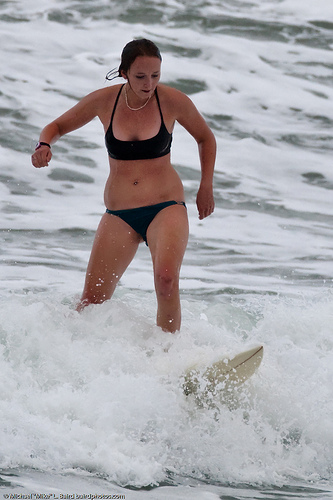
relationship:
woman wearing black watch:
[31, 34, 216, 334] [34, 141, 51, 150]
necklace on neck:
[124, 102, 144, 115] [125, 80, 135, 99]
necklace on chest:
[124, 102, 144, 115] [119, 115, 169, 142]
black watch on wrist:
[34, 141, 50, 150] [28, 137, 55, 154]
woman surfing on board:
[29, 34, 217, 335] [180, 343, 267, 401]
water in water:
[1, 0, 331, 496] [9, 38, 328, 467]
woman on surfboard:
[29, 34, 217, 335] [179, 339, 271, 401]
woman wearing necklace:
[31, 34, 216, 334] [121, 81, 152, 111]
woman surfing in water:
[29, 34, 217, 335] [284, 155, 318, 197]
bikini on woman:
[95, 199, 190, 240] [11, 23, 257, 278]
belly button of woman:
[129, 169, 152, 201] [29, 32, 231, 349]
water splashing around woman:
[1, 0, 332, 499] [31, 34, 216, 334]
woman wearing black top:
[31, 34, 216, 334] [104, 83, 172, 159]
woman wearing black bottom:
[31, 34, 216, 334] [104, 197, 185, 244]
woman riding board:
[31, 34, 216, 334] [180, 344, 263, 403]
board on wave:
[180, 344, 263, 403] [1, 285, 332, 487]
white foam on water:
[218, 87, 318, 255] [1, 0, 332, 499]